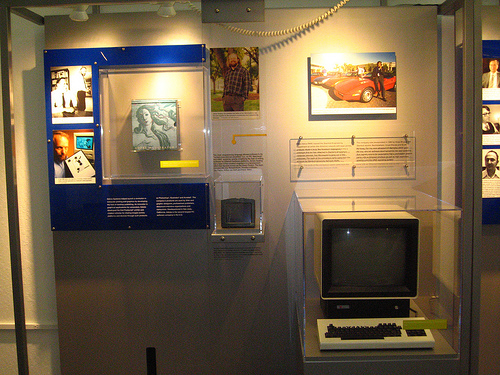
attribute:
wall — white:
[38, 21, 448, 357]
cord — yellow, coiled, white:
[230, 126, 280, 159]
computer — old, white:
[310, 210, 449, 355]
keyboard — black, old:
[321, 305, 427, 365]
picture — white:
[54, 70, 99, 123]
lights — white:
[71, 8, 182, 32]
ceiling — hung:
[44, 6, 439, 36]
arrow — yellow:
[229, 127, 274, 153]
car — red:
[332, 70, 400, 120]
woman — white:
[137, 109, 168, 151]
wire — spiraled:
[216, 17, 366, 45]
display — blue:
[90, 187, 201, 229]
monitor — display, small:
[332, 218, 411, 290]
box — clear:
[290, 138, 409, 178]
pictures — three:
[53, 68, 202, 193]